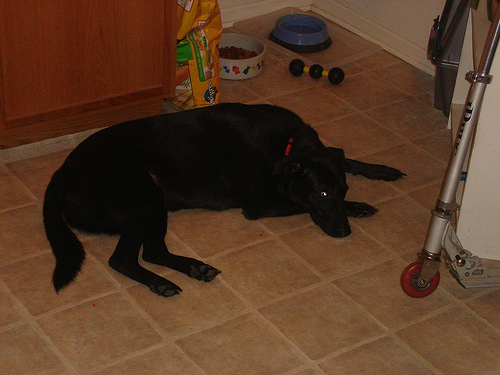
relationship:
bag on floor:
[167, 7, 226, 121] [1, 4, 496, 374]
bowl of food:
[209, 27, 266, 79] [176, 0, 221, 105]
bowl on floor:
[209, 27, 266, 79] [0, 152, 461, 372]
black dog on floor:
[49, 96, 355, 308] [1, 4, 496, 374]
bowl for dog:
[274, 9, 335, 55] [70, 132, 383, 223]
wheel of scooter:
[398, 262, 440, 300] [402, 16, 498, 298]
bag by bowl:
[167, 0, 224, 111] [209, 27, 266, 79]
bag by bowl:
[167, 0, 224, 111] [269, 6, 337, 52]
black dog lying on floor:
[43, 101, 408, 298] [1, 4, 496, 374]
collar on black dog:
[277, 127, 296, 166] [43, 101, 408, 298]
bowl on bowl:
[209, 33, 267, 81] [213, 27, 266, 82]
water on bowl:
[276, 23, 370, 73] [284, 7, 355, 44]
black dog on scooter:
[43, 101, 408, 298] [402, 16, 498, 298]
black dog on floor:
[43, 101, 408, 298] [306, 289, 371, 336]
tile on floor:
[30, 287, 167, 374] [1, 4, 496, 374]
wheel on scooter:
[400, 262, 440, 299] [398, 0, 500, 298]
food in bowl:
[220, 41, 253, 60] [271, 12, 342, 53]